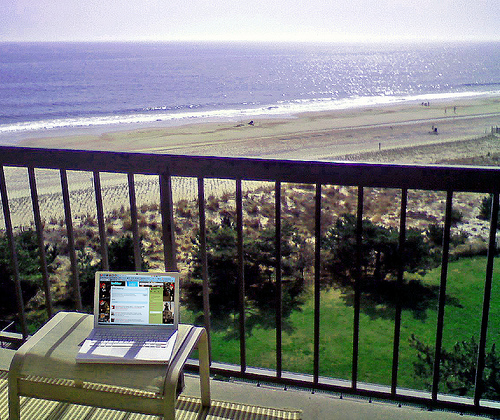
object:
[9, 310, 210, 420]
table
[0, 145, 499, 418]
balcony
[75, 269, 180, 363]
laptop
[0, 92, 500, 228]
sand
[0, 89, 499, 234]
beach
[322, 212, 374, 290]
tree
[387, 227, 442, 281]
tree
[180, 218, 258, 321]
tree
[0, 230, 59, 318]
tree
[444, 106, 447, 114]
person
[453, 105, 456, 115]
person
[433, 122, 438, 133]
person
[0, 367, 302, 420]
rug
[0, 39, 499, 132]
ocean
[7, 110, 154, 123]
wave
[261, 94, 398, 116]
wave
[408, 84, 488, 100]
wave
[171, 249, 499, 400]
lawn